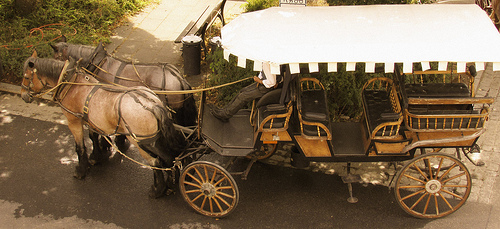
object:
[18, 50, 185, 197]
horse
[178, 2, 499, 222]
wagon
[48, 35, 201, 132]
horse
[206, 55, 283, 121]
driver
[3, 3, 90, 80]
foliage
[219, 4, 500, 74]
canopy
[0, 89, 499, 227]
road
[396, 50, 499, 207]
walkway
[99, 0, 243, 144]
walkway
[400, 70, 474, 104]
back seat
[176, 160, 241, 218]
left wheel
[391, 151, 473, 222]
left wheel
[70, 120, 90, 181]
leg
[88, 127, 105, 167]
leg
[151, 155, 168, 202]
leg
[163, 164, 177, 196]
leg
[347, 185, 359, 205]
step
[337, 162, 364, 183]
step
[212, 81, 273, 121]
bottom half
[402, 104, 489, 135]
back seat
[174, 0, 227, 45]
bench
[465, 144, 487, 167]
foot stool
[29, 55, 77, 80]
mane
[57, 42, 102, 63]
mane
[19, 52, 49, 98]
bridle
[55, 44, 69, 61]
bridle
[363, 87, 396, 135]
seat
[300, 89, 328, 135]
seat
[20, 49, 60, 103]
head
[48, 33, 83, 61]
head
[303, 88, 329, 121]
cushion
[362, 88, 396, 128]
cushion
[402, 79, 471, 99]
cushion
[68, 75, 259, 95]
rope